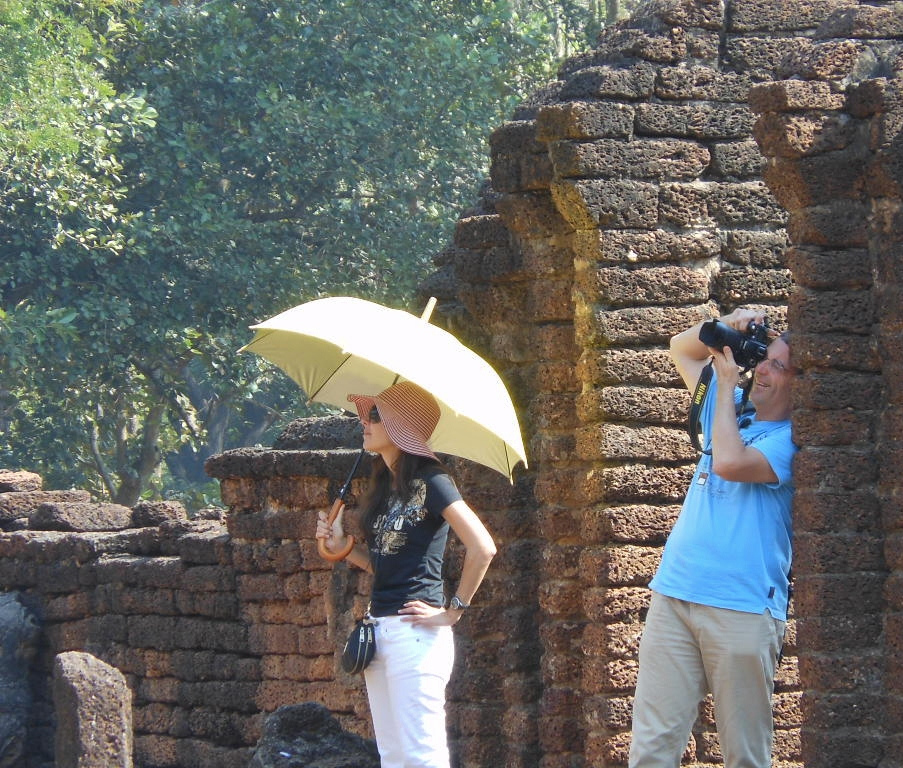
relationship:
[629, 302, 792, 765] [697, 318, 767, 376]
man looking through camera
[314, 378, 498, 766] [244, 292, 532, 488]
woman holding umbrella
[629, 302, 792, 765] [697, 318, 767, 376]
man using camera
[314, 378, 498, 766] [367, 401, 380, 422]
woman has shades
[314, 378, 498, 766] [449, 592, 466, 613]
woman has watch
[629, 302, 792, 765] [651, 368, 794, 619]
man has shirt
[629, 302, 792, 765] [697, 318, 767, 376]
man has camera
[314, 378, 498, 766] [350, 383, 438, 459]
woman has hat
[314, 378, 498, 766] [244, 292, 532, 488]
woman has umbrella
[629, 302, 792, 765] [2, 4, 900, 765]
man in scene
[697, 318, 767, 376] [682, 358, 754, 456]
camera has strap